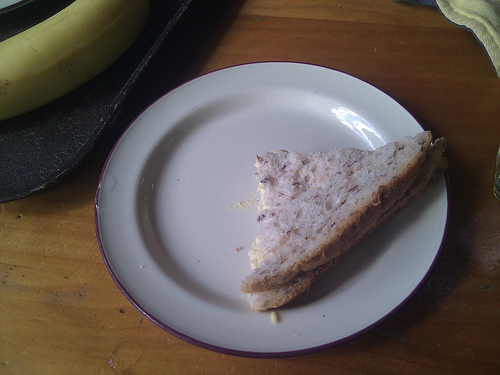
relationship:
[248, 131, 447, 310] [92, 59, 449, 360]
sandwich on top of plate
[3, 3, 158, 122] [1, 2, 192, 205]
banana on tray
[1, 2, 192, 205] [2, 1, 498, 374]
tray on top of table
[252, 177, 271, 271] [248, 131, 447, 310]
eggs on sandwich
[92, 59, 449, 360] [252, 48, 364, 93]
plate has rim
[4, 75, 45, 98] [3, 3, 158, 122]
spots on banana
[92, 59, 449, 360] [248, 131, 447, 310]
plate with sandwich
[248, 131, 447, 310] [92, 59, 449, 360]
sandwich on plate